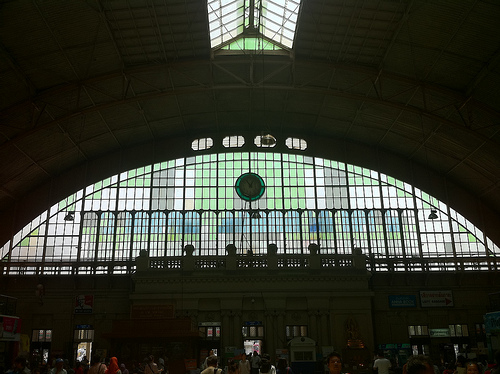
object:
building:
[0, 0, 500, 373]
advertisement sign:
[419, 290, 457, 308]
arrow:
[441, 294, 455, 309]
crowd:
[0, 349, 499, 372]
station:
[0, 0, 498, 373]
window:
[216, 33, 283, 53]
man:
[370, 351, 396, 373]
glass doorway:
[0, 151, 500, 271]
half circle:
[0, 150, 500, 275]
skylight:
[206, 0, 302, 54]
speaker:
[136, 247, 152, 258]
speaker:
[180, 245, 195, 256]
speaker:
[222, 242, 239, 254]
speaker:
[262, 242, 279, 254]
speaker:
[306, 242, 320, 253]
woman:
[102, 354, 124, 373]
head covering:
[108, 355, 118, 367]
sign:
[0, 317, 22, 342]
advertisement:
[72, 288, 89, 314]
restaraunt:
[125, 241, 375, 373]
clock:
[231, 172, 266, 203]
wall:
[0, 132, 500, 267]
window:
[285, 137, 307, 150]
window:
[252, 135, 277, 147]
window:
[221, 135, 244, 147]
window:
[192, 137, 213, 149]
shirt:
[373, 358, 393, 373]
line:
[0, 360, 500, 373]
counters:
[407, 336, 488, 346]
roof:
[7, 0, 494, 93]